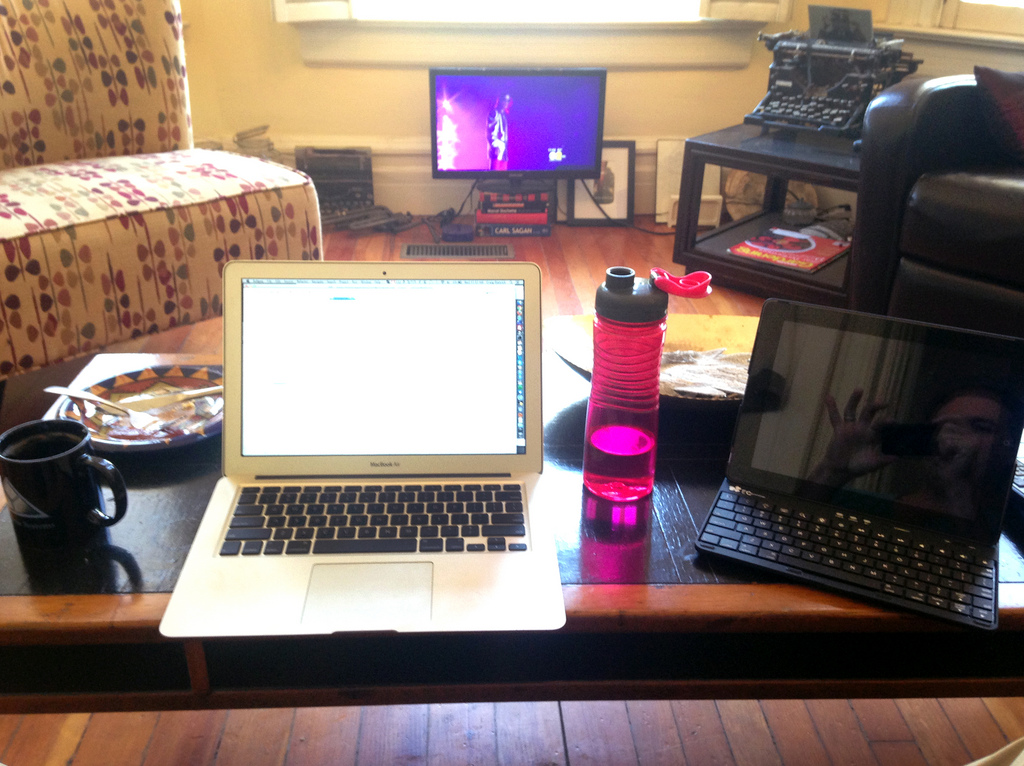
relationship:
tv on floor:
[422, 66, 609, 181] [68, 242, 911, 761]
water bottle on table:
[581, 265, 712, 542] [593, 534, 714, 628]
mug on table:
[0, 410, 138, 553] [571, 544, 729, 659]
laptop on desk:
[159, 260, 567, 636] [2, 353, 1015, 762]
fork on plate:
[43, 385, 185, 437] [100, 363, 222, 435]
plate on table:
[57, 359, 251, 449] [584, 535, 742, 641]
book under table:
[729, 215, 860, 279] [718, 127, 818, 173]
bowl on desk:
[560, 326, 780, 409] [0, 354, 1024, 717]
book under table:
[726, 226, 854, 274] [668, 86, 903, 299]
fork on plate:
[42, 378, 197, 445] [59, 359, 224, 452]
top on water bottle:
[595, 266, 713, 323] [577, 262, 711, 537]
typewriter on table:
[743, 2, 924, 143] [664, 113, 892, 313]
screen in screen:
[748, 319, 1017, 524] [740, 301, 1019, 529]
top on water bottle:
[585, 262, 672, 326] [577, 262, 711, 537]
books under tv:
[476, 190, 556, 237] [430, 61, 606, 183]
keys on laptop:
[214, 478, 534, 565] [159, 249, 581, 635]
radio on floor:
[288, 135, 380, 235] [2, 215, 1022, 760]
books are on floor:
[471, 180, 565, 226] [2, 215, 1022, 760]